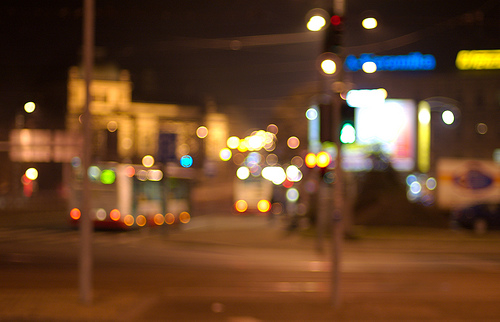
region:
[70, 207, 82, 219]
a blurry orange small light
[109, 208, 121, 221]
a blurry orange small light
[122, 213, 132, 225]
a blurry orange small light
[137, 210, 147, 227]
a blurry orange small light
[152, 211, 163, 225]
a blurry orange small light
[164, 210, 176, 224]
a blurry orange small light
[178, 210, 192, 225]
a blurry orange small light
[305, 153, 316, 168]
the bright small yellow light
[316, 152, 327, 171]
the bright small yellow light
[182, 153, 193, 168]
a bright green small light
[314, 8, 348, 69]
traffic light on the pole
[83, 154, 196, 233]
bus in the street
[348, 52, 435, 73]
blue light sign on the buidling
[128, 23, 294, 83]
power lines across the tree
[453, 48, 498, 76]
yellow light sign on a building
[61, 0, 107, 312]
pole on the corner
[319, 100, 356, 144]
walk sign light up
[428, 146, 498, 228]
truck on the street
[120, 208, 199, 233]
lights on the bus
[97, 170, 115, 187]
green light on the bus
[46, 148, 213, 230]
vehicle on the road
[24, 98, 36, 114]
light shining in the dark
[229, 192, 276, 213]
tail lights on the back of the vehicle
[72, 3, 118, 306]
pole sticking out of the ground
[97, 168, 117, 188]
green light shining on the back of the vehicle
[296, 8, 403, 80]
four bright white lights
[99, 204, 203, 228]
row of small lights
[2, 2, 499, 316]
scene is blurry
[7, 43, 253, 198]
building along the side of the road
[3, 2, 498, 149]
sky is pitch black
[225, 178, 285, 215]
lights on vehicle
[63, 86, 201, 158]
building in the background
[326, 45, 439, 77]
blue sign on building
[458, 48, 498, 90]
yellow sign on building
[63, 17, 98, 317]
post near sidewalk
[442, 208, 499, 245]
dark car going down road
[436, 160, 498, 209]
truck is parked on curb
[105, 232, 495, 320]
road is clear and dry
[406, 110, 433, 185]
tall yellow light in street